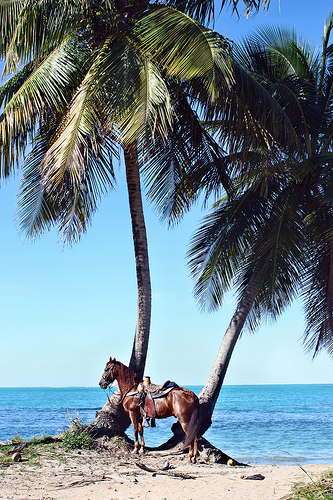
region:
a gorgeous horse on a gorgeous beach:
[1, 342, 320, 477]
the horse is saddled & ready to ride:
[60, 354, 217, 479]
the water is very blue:
[26, 397, 62, 438]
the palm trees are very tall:
[57, 94, 293, 439]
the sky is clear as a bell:
[55, 274, 120, 345]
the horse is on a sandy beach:
[76, 457, 164, 499]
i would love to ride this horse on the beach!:
[85, 349, 304, 477]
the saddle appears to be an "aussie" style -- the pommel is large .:
[134, 366, 164, 403]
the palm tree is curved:
[122, 237, 177, 373]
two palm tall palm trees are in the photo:
[73, 2, 299, 414]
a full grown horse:
[83, 347, 235, 478]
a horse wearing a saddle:
[99, 345, 220, 478]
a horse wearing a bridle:
[91, 354, 212, 470]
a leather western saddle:
[136, 366, 180, 442]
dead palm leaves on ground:
[118, 454, 200, 486]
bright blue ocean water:
[237, 379, 322, 451]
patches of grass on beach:
[19, 427, 98, 476]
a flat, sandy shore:
[67, 431, 307, 497]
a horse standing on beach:
[58, 341, 245, 488]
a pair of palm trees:
[15, 1, 320, 490]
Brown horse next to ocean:
[93, 358, 201, 436]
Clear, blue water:
[244, 378, 312, 445]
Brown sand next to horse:
[119, 466, 200, 498]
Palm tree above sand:
[218, 296, 284, 368]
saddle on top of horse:
[140, 378, 179, 404]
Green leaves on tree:
[266, 300, 332, 335]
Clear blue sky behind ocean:
[18, 318, 94, 400]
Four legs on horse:
[123, 414, 205, 459]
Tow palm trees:
[102, 304, 276, 375]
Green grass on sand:
[9, 434, 99, 473]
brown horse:
[89, 357, 211, 467]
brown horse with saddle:
[96, 357, 212, 464]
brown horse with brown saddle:
[92, 352, 221, 469]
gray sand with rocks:
[33, 457, 141, 494]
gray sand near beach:
[181, 464, 276, 497]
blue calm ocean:
[9, 392, 81, 418]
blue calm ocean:
[235, 391, 321, 447]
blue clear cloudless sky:
[7, 235, 129, 353]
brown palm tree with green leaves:
[5, 7, 239, 221]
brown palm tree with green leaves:
[198, 23, 320, 378]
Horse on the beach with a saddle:
[93, 354, 214, 465]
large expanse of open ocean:
[4, 384, 330, 457]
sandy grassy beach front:
[2, 430, 331, 498]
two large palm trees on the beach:
[4, 5, 322, 344]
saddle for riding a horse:
[130, 373, 169, 426]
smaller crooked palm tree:
[156, 114, 315, 431]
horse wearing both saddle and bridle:
[93, 352, 205, 464]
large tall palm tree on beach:
[8, 6, 182, 456]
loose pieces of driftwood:
[57, 459, 190, 483]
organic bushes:
[1, 429, 106, 466]